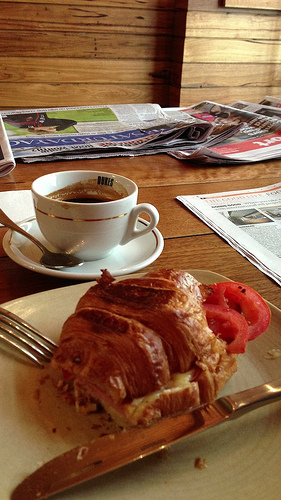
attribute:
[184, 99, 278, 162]
paper — sports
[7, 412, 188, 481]
knife — dirty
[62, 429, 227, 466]
fork — metal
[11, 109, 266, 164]
newpapers — scattered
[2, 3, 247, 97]
wall — wood, panels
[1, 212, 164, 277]
saucer — white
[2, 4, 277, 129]
wall — wood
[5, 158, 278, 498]
table — wooden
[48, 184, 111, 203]
coffee — black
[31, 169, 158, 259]
cup — gilded, white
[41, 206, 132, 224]
stripe — gold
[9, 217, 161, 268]
stripe — gold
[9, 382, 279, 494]
knife — stainless steel, bronze, butter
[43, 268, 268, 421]
sandwich — half eaten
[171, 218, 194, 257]
table — wood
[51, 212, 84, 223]
ring — gold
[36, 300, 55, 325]
plate — white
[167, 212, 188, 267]
table — wooden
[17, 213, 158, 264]
saucer — white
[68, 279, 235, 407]
sandwich — half-eaten